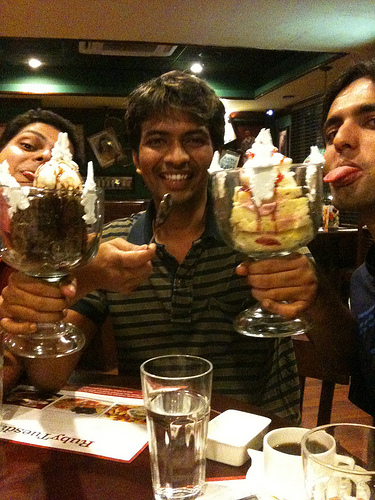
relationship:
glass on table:
[140, 354, 215, 498] [5, 371, 358, 499]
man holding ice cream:
[78, 72, 331, 405] [9, 124, 335, 360]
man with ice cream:
[78, 72, 331, 405] [9, 124, 335, 360]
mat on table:
[2, 362, 174, 468] [5, 371, 358, 499]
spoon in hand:
[126, 179, 178, 243] [90, 236, 176, 300]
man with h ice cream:
[78, 72, 331, 405] [9, 124, 335, 360]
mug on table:
[244, 419, 357, 492] [5, 371, 358, 499]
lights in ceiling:
[19, 52, 213, 84] [2, 2, 360, 104]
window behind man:
[275, 96, 371, 232] [78, 72, 331, 405]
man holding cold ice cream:
[78, 72, 331, 405] [9, 124, 335, 360]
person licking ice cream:
[293, 53, 375, 234] [9, 124, 335, 360]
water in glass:
[147, 388, 205, 493] [140, 354, 215, 498]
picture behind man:
[80, 119, 134, 173] [78, 72, 331, 405]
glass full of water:
[140, 354, 215, 498] [147, 388, 205, 493]